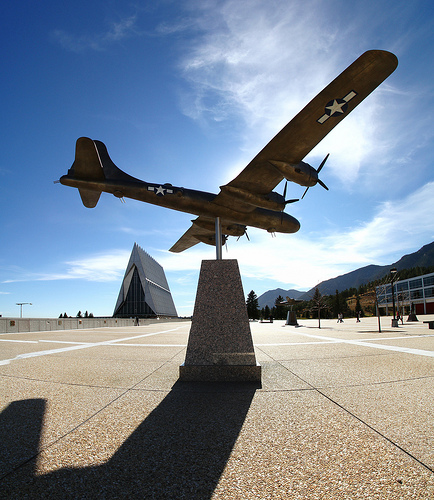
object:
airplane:
[52, 47, 400, 253]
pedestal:
[178, 258, 262, 384]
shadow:
[0, 376, 261, 500]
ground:
[0, 317, 434, 499]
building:
[374, 270, 433, 315]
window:
[377, 286, 386, 295]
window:
[396, 281, 409, 293]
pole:
[215, 216, 223, 261]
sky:
[0, 0, 432, 324]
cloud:
[164, 0, 434, 194]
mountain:
[246, 287, 307, 311]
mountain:
[298, 263, 387, 301]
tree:
[245, 289, 260, 321]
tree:
[303, 285, 333, 328]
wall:
[0, 318, 192, 334]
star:
[155, 186, 166, 196]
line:
[343, 340, 434, 371]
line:
[0, 344, 97, 367]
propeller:
[301, 152, 331, 200]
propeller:
[280, 180, 299, 225]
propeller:
[236, 225, 250, 242]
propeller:
[224, 234, 230, 252]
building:
[111, 241, 181, 318]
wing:
[209, 49, 398, 216]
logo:
[147, 184, 174, 197]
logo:
[316, 89, 359, 126]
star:
[325, 99, 346, 116]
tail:
[53, 136, 147, 210]